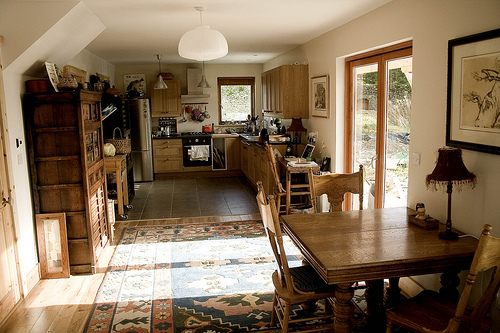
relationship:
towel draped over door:
[190, 147, 210, 162] [180, 137, 212, 164]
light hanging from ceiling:
[177, 25, 228, 62] [88, 2, 382, 59]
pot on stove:
[200, 125, 211, 134] [181, 131, 212, 166]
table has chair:
[275, 195, 490, 292] [254, 179, 344, 331]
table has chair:
[275, 195, 490, 292] [305, 163, 365, 214]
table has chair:
[275, 195, 490, 292] [380, 222, 493, 332]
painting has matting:
[444, 29, 498, 153] [463, 45, 472, 53]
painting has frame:
[444, 29, 498, 153] [444, 27, 493, 47]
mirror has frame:
[43, 221, 59, 269] [55, 211, 71, 281]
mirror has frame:
[43, 221, 59, 269] [443, 42, 459, 140]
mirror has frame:
[43, 221, 59, 269] [325, 75, 333, 115]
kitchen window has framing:
[217, 80, 258, 126] [217, 71, 257, 90]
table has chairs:
[258, 163, 499, 333] [308, 167, 369, 219]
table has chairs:
[258, 163, 499, 333] [247, 183, 350, 331]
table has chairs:
[258, 163, 499, 333] [402, 233, 498, 324]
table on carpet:
[258, 163, 499, 333] [75, 225, 407, 331]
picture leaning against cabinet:
[32, 210, 70, 283] [22, 74, 110, 276]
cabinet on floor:
[26, 71, 103, 267] [41, 279, 71, 331]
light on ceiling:
[171, 17, 234, 65] [248, 3, 324, 50]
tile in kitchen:
[142, 178, 238, 215] [117, 61, 326, 204]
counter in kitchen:
[212, 124, 269, 135] [119, 62, 311, 201]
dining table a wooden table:
[254, 144, 464, 333] [278, 203, 479, 328]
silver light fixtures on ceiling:
[153, 54, 166, 89] [153, 99, 236, 113]